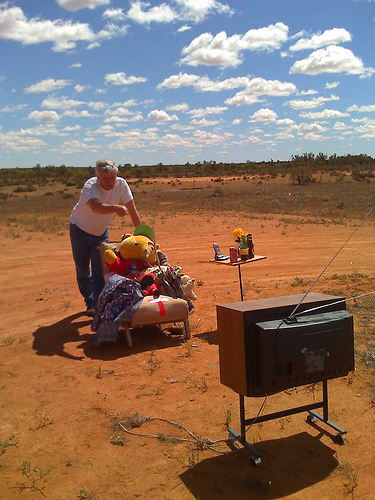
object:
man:
[69, 160, 142, 318]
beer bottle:
[247, 233, 254, 259]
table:
[210, 254, 267, 302]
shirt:
[70, 176, 134, 236]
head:
[95, 159, 118, 190]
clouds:
[0, 1, 375, 159]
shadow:
[178, 418, 345, 498]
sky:
[0, 0, 374, 169]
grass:
[344, 459, 363, 492]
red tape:
[148, 298, 169, 318]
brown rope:
[118, 417, 268, 454]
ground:
[0, 173, 375, 499]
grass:
[223, 408, 232, 429]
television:
[216, 292, 355, 398]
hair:
[96, 159, 119, 178]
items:
[213, 242, 229, 260]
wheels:
[307, 415, 343, 444]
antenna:
[288, 206, 374, 319]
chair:
[96, 240, 191, 349]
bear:
[104, 234, 161, 281]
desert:
[0, 176, 373, 500]